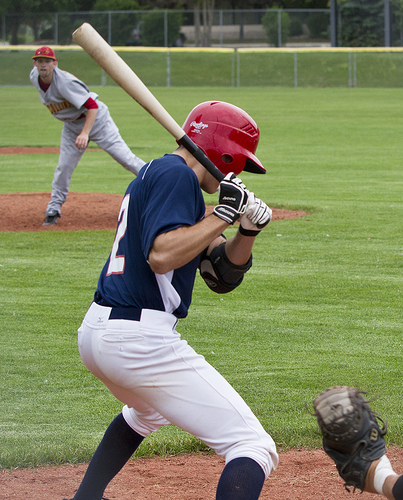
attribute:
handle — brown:
[176, 129, 248, 207]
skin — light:
[149, 147, 256, 275]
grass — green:
[0, 83, 402, 471]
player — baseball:
[28, 46, 148, 225]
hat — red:
[26, 45, 57, 58]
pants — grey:
[40, 110, 120, 224]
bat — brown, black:
[64, 20, 189, 133]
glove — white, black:
[214, 172, 245, 219]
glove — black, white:
[243, 183, 275, 227]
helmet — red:
[173, 99, 274, 173]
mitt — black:
[313, 394, 389, 469]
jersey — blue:
[99, 170, 197, 318]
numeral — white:
[105, 197, 134, 273]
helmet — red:
[181, 98, 260, 181]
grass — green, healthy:
[280, 230, 395, 384]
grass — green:
[274, 104, 396, 188]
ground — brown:
[23, 468, 331, 492]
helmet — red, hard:
[179, 100, 265, 178]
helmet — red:
[179, 96, 268, 174]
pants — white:
[75, 301, 241, 451]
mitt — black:
[313, 383, 393, 492]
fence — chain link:
[0, 5, 401, 48]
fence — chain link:
[0, 43, 402, 89]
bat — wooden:
[70, 20, 270, 227]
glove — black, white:
[215, 169, 247, 223]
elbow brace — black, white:
[198, 241, 251, 293]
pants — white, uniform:
[76, 301, 279, 476]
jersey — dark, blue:
[92, 153, 204, 317]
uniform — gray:
[29, 66, 141, 211]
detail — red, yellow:
[43, 98, 74, 113]